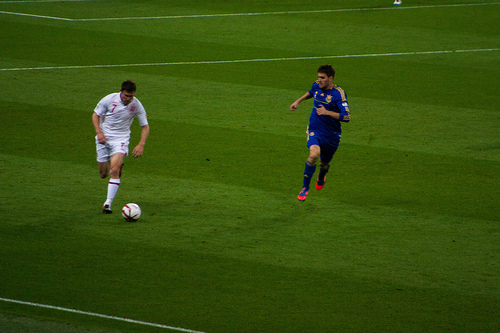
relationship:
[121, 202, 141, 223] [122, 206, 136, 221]
ball has stripes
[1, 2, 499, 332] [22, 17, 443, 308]
field for soccer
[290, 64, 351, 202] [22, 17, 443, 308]
man playing soccer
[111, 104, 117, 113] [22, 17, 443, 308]
number playing soccer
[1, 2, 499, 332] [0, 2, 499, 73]
field has lines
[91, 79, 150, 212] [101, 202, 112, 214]
man wearing shoes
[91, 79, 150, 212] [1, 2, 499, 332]
man playing on field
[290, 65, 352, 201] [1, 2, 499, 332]
man playing on field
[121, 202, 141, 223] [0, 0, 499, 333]
ball on field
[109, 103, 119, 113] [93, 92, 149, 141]
number on jersey